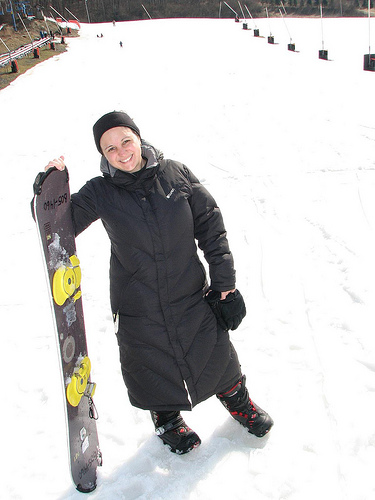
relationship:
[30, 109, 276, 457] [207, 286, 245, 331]
person wearing glove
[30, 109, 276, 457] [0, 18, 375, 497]
person standing on snow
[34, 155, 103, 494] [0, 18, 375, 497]
snowboard standing on snow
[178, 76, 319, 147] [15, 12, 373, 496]
snow covering ground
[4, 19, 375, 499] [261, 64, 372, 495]
snow covering ground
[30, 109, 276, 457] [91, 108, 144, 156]
person wearing hat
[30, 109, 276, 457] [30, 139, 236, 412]
person wearing coat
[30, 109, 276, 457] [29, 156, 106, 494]
person has snowboard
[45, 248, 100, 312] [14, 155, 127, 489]
foothold on snowboard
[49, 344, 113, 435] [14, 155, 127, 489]
foothold on snowboard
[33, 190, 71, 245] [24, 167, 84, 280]
number on snowboard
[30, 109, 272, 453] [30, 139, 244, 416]
person wearing coat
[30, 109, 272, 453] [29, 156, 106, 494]
person holding snowboard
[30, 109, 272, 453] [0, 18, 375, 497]
person standing on snow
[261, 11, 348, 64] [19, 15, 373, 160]
poles on snow course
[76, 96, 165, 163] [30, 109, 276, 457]
hat on person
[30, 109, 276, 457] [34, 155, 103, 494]
person by snowboard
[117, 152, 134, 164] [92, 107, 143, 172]
smile on woman's face